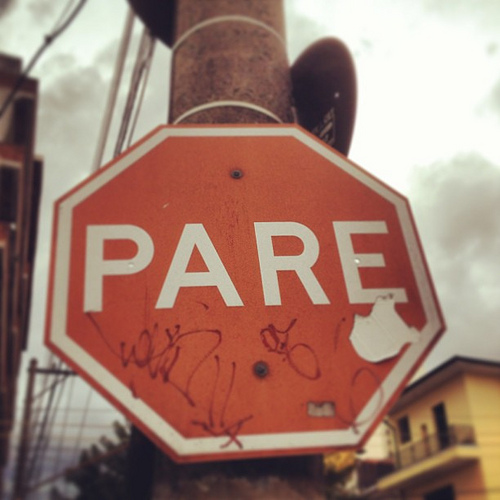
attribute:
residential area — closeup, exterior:
[1, 7, 499, 465]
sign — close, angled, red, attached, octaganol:
[55, 125, 445, 439]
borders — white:
[64, 127, 260, 209]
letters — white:
[83, 221, 400, 313]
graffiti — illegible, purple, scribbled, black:
[122, 311, 343, 407]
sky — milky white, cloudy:
[366, 29, 484, 193]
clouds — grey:
[414, 148, 498, 273]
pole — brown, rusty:
[171, 2, 299, 123]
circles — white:
[171, 13, 292, 50]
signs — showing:
[127, 0, 364, 154]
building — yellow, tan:
[379, 357, 499, 486]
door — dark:
[425, 400, 454, 447]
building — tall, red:
[3, 114, 48, 460]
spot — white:
[346, 295, 427, 366]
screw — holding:
[227, 165, 246, 185]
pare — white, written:
[86, 217, 407, 314]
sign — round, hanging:
[288, 38, 361, 156]